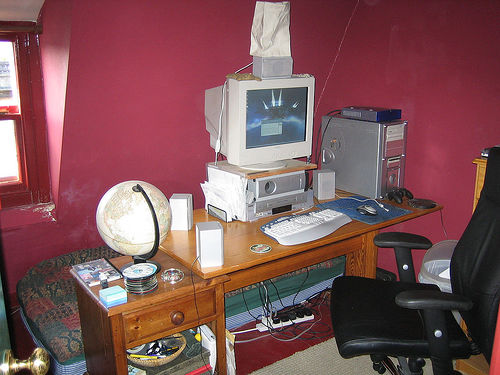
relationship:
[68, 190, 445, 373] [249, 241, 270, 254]
desk has cd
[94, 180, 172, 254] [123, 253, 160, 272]
globe with base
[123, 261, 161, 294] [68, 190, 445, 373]
cds on desk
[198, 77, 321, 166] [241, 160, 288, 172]
monitor on base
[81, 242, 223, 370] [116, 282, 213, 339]
table has drawer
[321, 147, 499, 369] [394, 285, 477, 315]
desk chair has handrest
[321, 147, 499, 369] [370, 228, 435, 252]
desk chair has handrest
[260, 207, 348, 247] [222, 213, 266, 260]
keyboard on desk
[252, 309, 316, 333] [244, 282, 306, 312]
power strip has cords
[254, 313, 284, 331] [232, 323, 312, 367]
power strip on floor